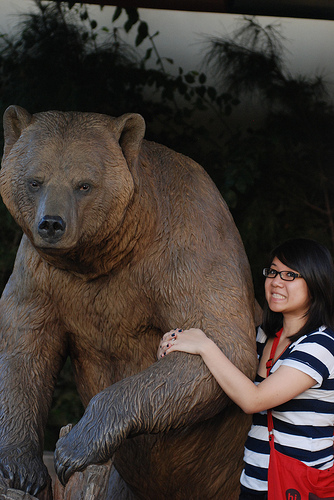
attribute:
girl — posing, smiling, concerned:
[149, 242, 333, 495]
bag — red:
[264, 439, 332, 497]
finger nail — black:
[168, 330, 180, 339]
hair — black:
[292, 250, 328, 332]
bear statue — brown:
[7, 99, 265, 386]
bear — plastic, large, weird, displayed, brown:
[5, 105, 248, 386]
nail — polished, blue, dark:
[170, 328, 188, 333]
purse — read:
[264, 360, 331, 500]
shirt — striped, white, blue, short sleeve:
[235, 329, 333, 499]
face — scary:
[263, 257, 314, 320]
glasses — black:
[259, 266, 321, 284]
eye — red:
[74, 183, 98, 194]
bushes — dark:
[17, 1, 329, 284]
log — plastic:
[0, 453, 140, 500]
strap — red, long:
[266, 336, 276, 451]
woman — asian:
[155, 251, 333, 499]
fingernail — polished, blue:
[154, 343, 165, 350]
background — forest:
[9, 4, 334, 244]